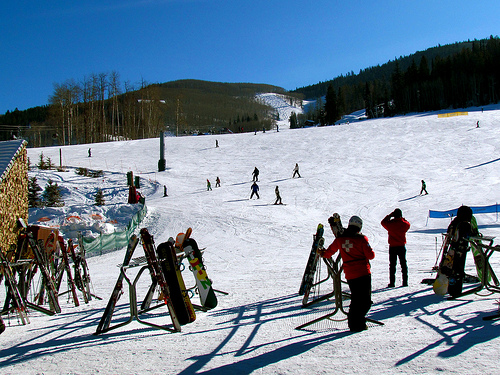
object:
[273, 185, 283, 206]
person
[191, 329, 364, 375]
long shadow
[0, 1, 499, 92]
cloud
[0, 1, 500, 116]
sky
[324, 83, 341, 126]
evergreen trees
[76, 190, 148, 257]
wall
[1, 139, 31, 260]
building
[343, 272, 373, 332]
pants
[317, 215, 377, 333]
person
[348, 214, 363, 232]
hat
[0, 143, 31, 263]
wall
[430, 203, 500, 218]
banner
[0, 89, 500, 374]
ground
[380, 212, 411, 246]
jacket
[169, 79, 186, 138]
trees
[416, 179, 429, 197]
person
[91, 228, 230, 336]
rack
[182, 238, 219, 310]
snowboard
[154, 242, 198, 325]
snowboard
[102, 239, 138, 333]
skis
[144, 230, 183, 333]
skis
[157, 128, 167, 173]
pole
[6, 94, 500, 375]
snow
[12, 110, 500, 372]
ski slope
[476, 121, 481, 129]
person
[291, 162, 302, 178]
person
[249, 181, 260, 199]
person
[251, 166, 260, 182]
person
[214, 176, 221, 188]
person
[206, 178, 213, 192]
person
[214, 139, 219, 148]
person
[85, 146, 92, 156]
person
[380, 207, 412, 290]
person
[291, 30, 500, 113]
mountain